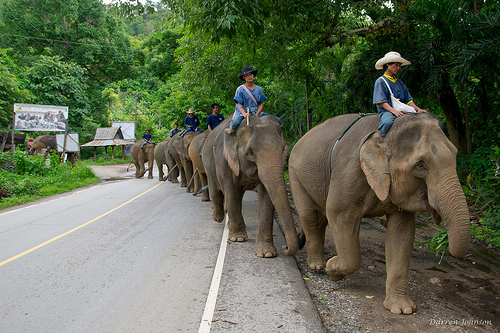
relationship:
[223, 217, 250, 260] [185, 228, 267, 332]
feet straddling white line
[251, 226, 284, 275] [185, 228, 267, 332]
feet straddling white line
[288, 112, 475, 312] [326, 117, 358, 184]
elephant has strap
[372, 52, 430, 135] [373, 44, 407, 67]
man wearing hat.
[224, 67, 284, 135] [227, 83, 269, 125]
man wearing suit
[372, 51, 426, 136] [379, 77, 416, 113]
man has bag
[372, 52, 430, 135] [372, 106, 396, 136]
man wearing jeans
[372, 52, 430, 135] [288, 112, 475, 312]
man riding elephant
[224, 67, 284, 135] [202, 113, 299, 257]
man riding elephant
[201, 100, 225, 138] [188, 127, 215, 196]
people riding elephant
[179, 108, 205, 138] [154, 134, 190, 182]
man riding elephant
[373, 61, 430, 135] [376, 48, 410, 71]
man wearing hat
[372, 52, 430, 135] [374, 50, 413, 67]
man wearing white hat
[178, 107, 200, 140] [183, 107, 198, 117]
man wearing hat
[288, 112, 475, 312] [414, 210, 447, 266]
elephant holding grass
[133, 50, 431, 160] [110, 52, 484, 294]
men riding elephants.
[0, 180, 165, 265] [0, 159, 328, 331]
line in road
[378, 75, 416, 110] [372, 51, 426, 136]
satchel around man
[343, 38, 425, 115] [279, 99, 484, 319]
man riding elephant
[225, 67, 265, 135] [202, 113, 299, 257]
man riding elephant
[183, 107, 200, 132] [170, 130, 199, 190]
man riding elephant